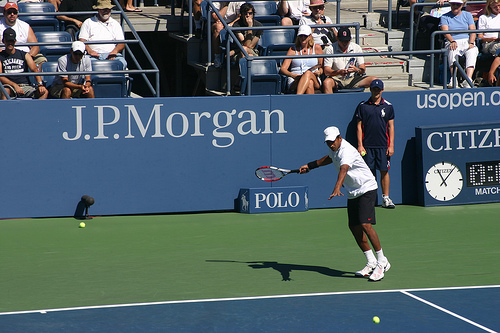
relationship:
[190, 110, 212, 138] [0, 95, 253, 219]
letter on wall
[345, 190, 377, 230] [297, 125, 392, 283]
tennis shorts on a player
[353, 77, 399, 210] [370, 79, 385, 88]
guy wearing hat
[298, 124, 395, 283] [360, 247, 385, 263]
guy wearing white socks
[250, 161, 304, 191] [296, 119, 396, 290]
racket held by player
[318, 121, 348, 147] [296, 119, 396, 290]
cap on player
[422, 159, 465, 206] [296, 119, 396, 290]
clock behind player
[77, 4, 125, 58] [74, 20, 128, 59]
man wearing shirt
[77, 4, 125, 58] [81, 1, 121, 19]
man wearing hat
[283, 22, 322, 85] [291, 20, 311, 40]
woman wearing cap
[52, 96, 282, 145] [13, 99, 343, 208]
name printed on background